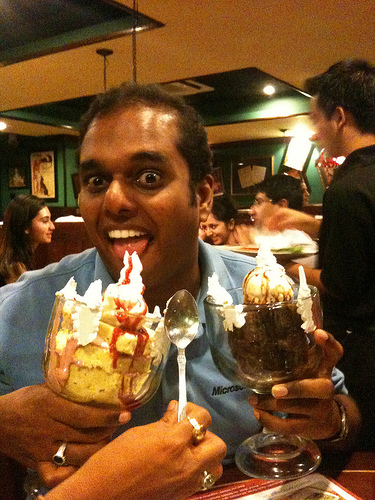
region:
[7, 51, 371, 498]
A man holding two ice cream sundaes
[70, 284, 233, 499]
A woman's hand holding a spoon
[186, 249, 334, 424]
A chocolate brownie with vanilla ice cream and whipped cream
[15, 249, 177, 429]
Cheesecake with vanilla ice cream and whipped cream and raspberry sauce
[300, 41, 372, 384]
A waiter walking by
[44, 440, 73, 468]
A silver and black ring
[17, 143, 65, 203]
Picture frame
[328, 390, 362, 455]
Silver watch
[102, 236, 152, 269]
The man's tongue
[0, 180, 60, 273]
A girl sitting at a table behind the man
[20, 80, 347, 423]
A guy is holding two large glasses with desserts in them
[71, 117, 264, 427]
The guy is wearing a blue collared shirt that says Microsoft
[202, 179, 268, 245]
Young woman at a table in the background is smiling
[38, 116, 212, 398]
The guy is sticking his tongue out towards the whipped cream on top of the cake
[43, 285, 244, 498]
A woman's hand is holding a silver spoon in between the desserts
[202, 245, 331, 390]
Chocolate cake with ice cream on top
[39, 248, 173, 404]
Yellow cake with whipped cream and strawberry sauce on top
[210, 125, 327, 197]
Artwork hanging on the wall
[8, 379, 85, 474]
Man is wearing a silver ring with a black stone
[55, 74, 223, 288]
Guy with very straight, white teeth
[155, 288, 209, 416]
Bright silver spoon in someone's hand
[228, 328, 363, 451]
Man's left hand with a cup in it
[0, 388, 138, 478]
Man's right hand with a cup in it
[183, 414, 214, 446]
Large metal ring on person's hand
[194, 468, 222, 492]
Large metal ring on person's hand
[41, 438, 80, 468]
Large metal ring on man's hand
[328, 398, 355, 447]
Metal bracelet on man's wrist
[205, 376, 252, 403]
Part of a black lettered logo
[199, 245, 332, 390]
Chocolate and vanilla dessert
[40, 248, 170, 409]
Vanilla and strawberry dessert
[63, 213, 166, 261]
the man`s mouth is open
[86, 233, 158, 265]
the man`s tongue is out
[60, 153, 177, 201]
the man`s eyes are open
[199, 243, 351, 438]
man is holding a big glass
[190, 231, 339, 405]
the glass has desert in it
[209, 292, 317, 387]
the desert is brown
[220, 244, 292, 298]
there is vanilla ice cream on top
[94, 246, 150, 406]
there is red sauce on the ice cream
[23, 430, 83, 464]
man is wearing a ring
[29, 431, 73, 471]
the ring is silver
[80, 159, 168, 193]
A pair of crazy eyes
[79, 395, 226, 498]
A couple of rings on a womans hand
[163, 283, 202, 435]
A silver spoon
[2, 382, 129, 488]
A man wearing a ring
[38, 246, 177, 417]
A cup of strawberry shortcake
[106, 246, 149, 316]
Whipped cream with strawberry sauce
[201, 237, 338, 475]
A cup of chocolate cake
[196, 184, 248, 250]
A woman smiling while listening to someone else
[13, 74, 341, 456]
A man pretending to lick whipped cream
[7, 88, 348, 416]
A man posing for a picture with crazy eyes